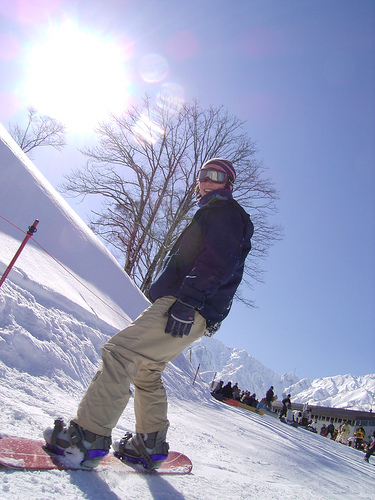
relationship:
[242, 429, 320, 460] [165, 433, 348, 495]
snow on ground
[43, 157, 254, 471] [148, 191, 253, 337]
individual wearing coat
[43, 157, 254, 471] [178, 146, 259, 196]
individual wearing hat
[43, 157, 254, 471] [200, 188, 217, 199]
individual has smile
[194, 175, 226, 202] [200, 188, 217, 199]
mouth has openmouthed smile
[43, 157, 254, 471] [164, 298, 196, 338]
individual wearing blue gloves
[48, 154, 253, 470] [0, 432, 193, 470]
individual on a snowboard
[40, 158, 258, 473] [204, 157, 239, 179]
snowboarder wearing a hat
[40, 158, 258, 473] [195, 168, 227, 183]
snowboarder wearing eyewear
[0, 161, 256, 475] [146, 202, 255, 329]
snowboarder wearing jacket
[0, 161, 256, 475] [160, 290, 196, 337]
snowboarder wearing glove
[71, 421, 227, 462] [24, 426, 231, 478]
boots on snowboard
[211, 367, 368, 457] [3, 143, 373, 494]
people enjoying snow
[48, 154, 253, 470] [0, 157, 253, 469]
individual wearing snowboard gear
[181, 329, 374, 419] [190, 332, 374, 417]
mountains in distance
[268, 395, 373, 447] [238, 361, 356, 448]
building in background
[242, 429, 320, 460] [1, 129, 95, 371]
snow pushed in pile